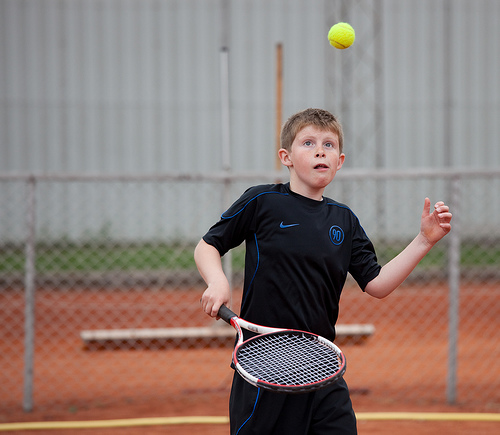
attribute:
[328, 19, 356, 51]
ball — yellow, flying, green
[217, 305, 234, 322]
tape — black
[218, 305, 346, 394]
racket — red, white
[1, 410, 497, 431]
line — yellow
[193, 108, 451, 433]
boy — playing, young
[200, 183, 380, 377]
shirt — black, nike, blue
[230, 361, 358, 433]
shorts — black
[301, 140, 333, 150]
eyes — blue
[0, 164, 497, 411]
fence — metal, chain link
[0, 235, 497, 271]
grass — green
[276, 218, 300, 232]
logo — nike, blue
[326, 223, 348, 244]
number — blue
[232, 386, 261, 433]
stripe — blue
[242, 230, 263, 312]
stripe — blue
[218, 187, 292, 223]
stripe — blue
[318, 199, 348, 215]
stripe — blue